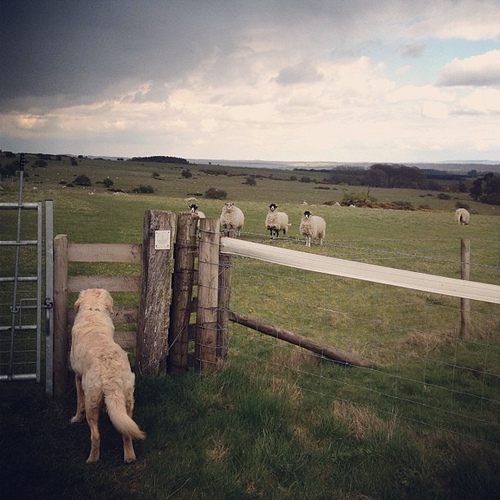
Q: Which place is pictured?
A: It is a field.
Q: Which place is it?
A: It is a field.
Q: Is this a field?
A: Yes, it is a field.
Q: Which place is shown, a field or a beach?
A: It is a field.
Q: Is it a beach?
A: No, it is a field.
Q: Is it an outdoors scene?
A: Yes, it is outdoors.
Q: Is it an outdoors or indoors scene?
A: It is outdoors.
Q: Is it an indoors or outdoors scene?
A: It is outdoors.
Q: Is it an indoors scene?
A: No, it is outdoors.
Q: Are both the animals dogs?
A: No, they are sheep and dogs.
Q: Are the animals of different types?
A: Yes, they are sheep and dogs.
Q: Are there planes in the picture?
A: No, there are no planes.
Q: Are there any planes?
A: No, there are no planes.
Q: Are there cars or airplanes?
A: No, there are no airplanes or cars.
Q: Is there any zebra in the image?
A: No, there are no zebras.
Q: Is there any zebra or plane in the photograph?
A: No, there are no zebras or airplanes.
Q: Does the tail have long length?
A: Yes, the tail is long.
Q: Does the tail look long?
A: Yes, the tail is long.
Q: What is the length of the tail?
A: The tail is long.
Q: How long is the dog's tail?
A: The tail is long.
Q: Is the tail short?
A: No, the tail is long.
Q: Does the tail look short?
A: No, the tail is long.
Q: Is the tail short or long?
A: The tail is long.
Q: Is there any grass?
A: Yes, there is grass.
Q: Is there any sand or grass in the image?
A: Yes, there is grass.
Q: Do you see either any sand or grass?
A: Yes, there is grass.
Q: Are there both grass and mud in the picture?
A: No, there is grass but no mud.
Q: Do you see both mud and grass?
A: No, there is grass but no mud.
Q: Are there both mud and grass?
A: No, there is grass but no mud.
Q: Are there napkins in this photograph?
A: No, there are no napkins.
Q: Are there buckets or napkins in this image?
A: No, there are no napkins or buckets.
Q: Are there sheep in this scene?
A: Yes, there is a sheep.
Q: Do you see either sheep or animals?
A: Yes, there is a sheep.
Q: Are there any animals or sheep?
A: Yes, there is a sheep.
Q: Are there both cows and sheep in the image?
A: No, there is a sheep but no cows.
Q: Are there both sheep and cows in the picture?
A: No, there is a sheep but no cows.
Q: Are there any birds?
A: No, there are no birds.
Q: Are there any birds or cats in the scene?
A: No, there are no birds or cats.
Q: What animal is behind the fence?
A: The animal is a sheep.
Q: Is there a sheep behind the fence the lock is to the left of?
A: Yes, there is a sheep behind the fence.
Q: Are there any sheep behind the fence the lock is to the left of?
A: Yes, there is a sheep behind the fence.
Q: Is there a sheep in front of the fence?
A: No, the sheep is behind the fence.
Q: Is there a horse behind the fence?
A: No, there is a sheep behind the fence.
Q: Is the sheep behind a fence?
A: Yes, the sheep is behind a fence.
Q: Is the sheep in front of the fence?
A: No, the sheep is behind the fence.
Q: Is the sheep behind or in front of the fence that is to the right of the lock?
A: The sheep is behind the fence.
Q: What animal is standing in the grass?
A: The sheep is standing in the grass.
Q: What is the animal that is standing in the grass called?
A: The animal is a sheep.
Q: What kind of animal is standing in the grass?
A: The animal is a sheep.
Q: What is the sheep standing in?
A: The sheep is standing in the grass.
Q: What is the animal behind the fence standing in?
A: The sheep is standing in the grass.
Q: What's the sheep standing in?
A: The sheep is standing in the grass.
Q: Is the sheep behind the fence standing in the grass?
A: Yes, the sheep is standing in the grass.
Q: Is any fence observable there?
A: Yes, there is a fence.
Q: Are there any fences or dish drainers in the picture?
A: Yes, there is a fence.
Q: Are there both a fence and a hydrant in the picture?
A: No, there is a fence but no fire hydrants.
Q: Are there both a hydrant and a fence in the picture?
A: No, there is a fence but no fire hydrants.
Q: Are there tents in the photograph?
A: No, there are no tents.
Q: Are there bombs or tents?
A: No, there are no tents or bombs.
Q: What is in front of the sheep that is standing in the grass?
A: The fence is in front of the sheep.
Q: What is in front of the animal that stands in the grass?
A: The fence is in front of the sheep.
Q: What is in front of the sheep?
A: The fence is in front of the sheep.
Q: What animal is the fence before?
A: The fence is in front of the sheep.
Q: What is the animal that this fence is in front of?
A: The animal is a sheep.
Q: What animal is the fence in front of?
A: The fence is in front of the sheep.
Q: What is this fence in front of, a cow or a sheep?
A: The fence is in front of a sheep.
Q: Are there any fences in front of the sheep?
A: Yes, there is a fence in front of the sheep.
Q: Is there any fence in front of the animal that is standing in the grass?
A: Yes, there is a fence in front of the sheep.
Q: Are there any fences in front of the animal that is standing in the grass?
A: Yes, there is a fence in front of the sheep.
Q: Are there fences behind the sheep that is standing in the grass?
A: No, the fence is in front of the sheep.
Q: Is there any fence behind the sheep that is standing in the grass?
A: No, the fence is in front of the sheep.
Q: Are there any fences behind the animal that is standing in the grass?
A: No, the fence is in front of the sheep.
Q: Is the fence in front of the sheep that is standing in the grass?
A: Yes, the fence is in front of the sheep.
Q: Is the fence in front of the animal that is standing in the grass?
A: Yes, the fence is in front of the sheep.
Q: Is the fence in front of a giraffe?
A: No, the fence is in front of the sheep.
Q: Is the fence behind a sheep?
A: No, the fence is in front of a sheep.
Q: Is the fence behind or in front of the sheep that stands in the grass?
A: The fence is in front of the sheep.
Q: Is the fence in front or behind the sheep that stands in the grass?
A: The fence is in front of the sheep.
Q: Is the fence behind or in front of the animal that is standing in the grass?
A: The fence is in front of the sheep.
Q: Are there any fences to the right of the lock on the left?
A: Yes, there is a fence to the right of the lock.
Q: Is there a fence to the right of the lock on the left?
A: Yes, there is a fence to the right of the lock.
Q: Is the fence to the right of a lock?
A: Yes, the fence is to the right of a lock.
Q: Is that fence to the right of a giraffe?
A: No, the fence is to the right of a lock.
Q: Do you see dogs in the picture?
A: Yes, there is a dog.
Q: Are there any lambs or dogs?
A: Yes, there is a dog.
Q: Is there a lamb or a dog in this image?
A: Yes, there is a dog.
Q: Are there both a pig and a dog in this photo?
A: No, there is a dog but no pigs.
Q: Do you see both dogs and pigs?
A: No, there is a dog but no pigs.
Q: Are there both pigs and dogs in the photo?
A: No, there is a dog but no pigs.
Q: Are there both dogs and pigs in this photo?
A: No, there is a dog but no pigs.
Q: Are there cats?
A: No, there are no cats.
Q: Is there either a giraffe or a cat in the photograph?
A: No, there are no cats or giraffes.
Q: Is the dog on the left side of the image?
A: Yes, the dog is on the left of the image.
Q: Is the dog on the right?
A: No, the dog is on the left of the image.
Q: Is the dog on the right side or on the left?
A: The dog is on the left of the image.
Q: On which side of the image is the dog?
A: The dog is on the left of the image.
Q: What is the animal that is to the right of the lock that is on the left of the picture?
A: The animal is a dog.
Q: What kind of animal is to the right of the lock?
A: The animal is a dog.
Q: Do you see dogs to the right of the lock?
A: Yes, there is a dog to the right of the lock.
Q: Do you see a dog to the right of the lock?
A: Yes, there is a dog to the right of the lock.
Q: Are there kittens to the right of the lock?
A: No, there is a dog to the right of the lock.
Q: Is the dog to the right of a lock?
A: Yes, the dog is to the right of a lock.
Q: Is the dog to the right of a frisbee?
A: No, the dog is to the right of a lock.